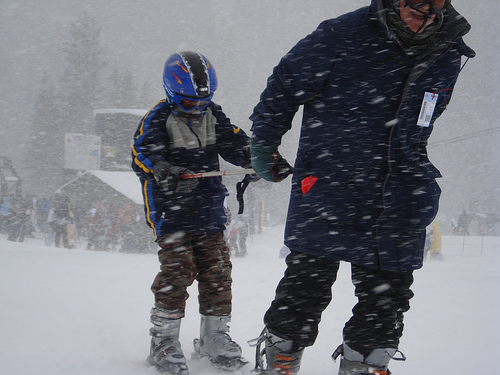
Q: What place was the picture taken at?
A: It was taken at the field.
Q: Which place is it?
A: It is a field.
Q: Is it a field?
A: Yes, it is a field.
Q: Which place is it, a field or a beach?
A: It is a field.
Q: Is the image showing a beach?
A: No, the picture is showing a field.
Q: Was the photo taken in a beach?
A: No, the picture was taken in a field.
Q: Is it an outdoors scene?
A: Yes, it is outdoors.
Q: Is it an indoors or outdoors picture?
A: It is outdoors.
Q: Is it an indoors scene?
A: No, it is outdoors.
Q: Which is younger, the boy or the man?
A: The boy is younger than the man.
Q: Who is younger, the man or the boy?
A: The boy is younger than the man.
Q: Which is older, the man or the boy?
A: The man is older than the boy.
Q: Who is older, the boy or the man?
A: The man is older than the boy.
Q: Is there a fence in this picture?
A: Yes, there is a fence.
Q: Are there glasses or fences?
A: Yes, there is a fence.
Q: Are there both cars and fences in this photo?
A: No, there is a fence but no cars.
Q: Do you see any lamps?
A: No, there are no lamps.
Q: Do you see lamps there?
A: No, there are no lamps.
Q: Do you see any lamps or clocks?
A: No, there are no lamps or clocks.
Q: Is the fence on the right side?
A: Yes, the fence is on the right of the image.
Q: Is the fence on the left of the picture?
A: No, the fence is on the right of the image.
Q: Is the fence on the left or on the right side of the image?
A: The fence is on the right of the image.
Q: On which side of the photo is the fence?
A: The fence is on the right of the image.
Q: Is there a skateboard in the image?
A: No, there are no skateboards.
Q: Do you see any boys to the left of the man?
A: Yes, there is a boy to the left of the man.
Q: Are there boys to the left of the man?
A: Yes, there is a boy to the left of the man.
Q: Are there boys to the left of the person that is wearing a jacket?
A: Yes, there is a boy to the left of the man.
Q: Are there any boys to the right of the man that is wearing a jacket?
A: No, the boy is to the left of the man.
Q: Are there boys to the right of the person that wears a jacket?
A: No, the boy is to the left of the man.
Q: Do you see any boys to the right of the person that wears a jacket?
A: No, the boy is to the left of the man.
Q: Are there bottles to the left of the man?
A: No, there is a boy to the left of the man.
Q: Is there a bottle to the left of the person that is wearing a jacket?
A: No, there is a boy to the left of the man.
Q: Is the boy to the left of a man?
A: Yes, the boy is to the left of a man.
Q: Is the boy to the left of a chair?
A: No, the boy is to the left of a man.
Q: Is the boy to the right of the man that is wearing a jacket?
A: No, the boy is to the left of the man.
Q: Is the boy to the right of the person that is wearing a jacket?
A: No, the boy is to the left of the man.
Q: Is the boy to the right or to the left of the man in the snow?
A: The boy is to the left of the man.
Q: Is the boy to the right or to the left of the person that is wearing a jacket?
A: The boy is to the left of the man.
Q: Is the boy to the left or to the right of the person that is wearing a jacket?
A: The boy is to the left of the man.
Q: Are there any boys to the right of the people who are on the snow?
A: Yes, there is a boy to the right of the people.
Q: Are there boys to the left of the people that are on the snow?
A: No, the boy is to the right of the people.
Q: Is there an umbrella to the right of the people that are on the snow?
A: No, there is a boy to the right of the people.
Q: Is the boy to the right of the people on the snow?
A: Yes, the boy is to the right of the people.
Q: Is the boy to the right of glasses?
A: No, the boy is to the right of the people.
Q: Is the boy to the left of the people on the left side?
A: No, the boy is to the right of the people.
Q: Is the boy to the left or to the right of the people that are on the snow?
A: The boy is to the right of the people.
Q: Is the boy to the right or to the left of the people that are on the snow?
A: The boy is to the right of the people.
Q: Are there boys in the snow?
A: Yes, there is a boy in the snow.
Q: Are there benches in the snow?
A: No, there is a boy in the snow.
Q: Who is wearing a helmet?
A: The boy is wearing a helmet.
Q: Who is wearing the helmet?
A: The boy is wearing a helmet.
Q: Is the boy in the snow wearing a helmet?
A: Yes, the boy is wearing a helmet.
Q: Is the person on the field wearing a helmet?
A: Yes, the boy is wearing a helmet.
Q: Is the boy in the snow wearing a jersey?
A: No, the boy is wearing a helmet.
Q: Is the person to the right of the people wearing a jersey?
A: No, the boy is wearing a helmet.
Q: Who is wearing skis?
A: The boy is wearing skis.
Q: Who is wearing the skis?
A: The boy is wearing skis.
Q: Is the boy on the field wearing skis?
A: Yes, the boy is wearing skis.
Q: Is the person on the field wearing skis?
A: Yes, the boy is wearing skis.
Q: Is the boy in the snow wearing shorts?
A: No, the boy is wearing skis.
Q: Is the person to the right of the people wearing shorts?
A: No, the boy is wearing skis.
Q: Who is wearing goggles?
A: The boy is wearing goggles.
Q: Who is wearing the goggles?
A: The boy is wearing goggles.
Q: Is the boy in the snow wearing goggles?
A: Yes, the boy is wearing goggles.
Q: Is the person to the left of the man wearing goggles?
A: Yes, the boy is wearing goggles.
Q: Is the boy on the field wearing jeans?
A: No, the boy is wearing goggles.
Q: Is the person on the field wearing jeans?
A: No, the boy is wearing goggles.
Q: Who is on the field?
A: The boy is on the field.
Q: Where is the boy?
A: The boy is on the field.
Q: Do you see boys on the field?
A: Yes, there is a boy on the field.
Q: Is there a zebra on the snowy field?
A: No, there is a boy on the field.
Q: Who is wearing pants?
A: The boy is wearing pants.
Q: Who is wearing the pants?
A: The boy is wearing pants.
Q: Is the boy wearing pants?
A: Yes, the boy is wearing pants.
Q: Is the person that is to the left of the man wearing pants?
A: Yes, the boy is wearing pants.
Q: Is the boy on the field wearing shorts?
A: No, the boy is wearing pants.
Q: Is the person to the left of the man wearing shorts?
A: No, the boy is wearing pants.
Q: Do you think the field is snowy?
A: Yes, the field is snowy.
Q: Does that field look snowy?
A: Yes, the field is snowy.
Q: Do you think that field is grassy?
A: No, the field is snowy.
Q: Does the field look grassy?
A: No, the field is snowy.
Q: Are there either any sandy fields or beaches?
A: No, there is a field but it is snowy.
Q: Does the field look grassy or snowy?
A: The field is snowy.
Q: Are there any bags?
A: No, there are no bags.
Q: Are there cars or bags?
A: No, there are no bags or cars.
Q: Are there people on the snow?
A: Yes, there are people on the snow.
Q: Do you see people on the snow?
A: Yes, there are people on the snow.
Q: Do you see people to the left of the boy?
A: Yes, there are people to the left of the boy.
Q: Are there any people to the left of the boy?
A: Yes, there are people to the left of the boy.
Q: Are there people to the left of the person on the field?
A: Yes, there are people to the left of the boy.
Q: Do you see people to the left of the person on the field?
A: Yes, there are people to the left of the boy.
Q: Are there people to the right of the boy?
A: No, the people are to the left of the boy.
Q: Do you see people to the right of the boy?
A: No, the people are to the left of the boy.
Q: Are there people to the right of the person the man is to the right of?
A: No, the people are to the left of the boy.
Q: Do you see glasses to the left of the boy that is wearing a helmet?
A: No, there are people to the left of the boy.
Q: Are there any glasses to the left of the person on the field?
A: No, there are people to the left of the boy.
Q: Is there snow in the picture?
A: Yes, there is snow.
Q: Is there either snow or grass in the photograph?
A: Yes, there is snow.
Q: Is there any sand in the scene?
A: No, there is no sand.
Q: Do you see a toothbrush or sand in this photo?
A: No, there are no sand or toothbrushes.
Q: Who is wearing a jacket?
A: The man is wearing a jacket.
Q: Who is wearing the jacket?
A: The man is wearing a jacket.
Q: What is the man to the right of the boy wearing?
A: The man is wearing a jacket.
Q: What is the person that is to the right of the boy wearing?
A: The man is wearing a jacket.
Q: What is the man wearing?
A: The man is wearing a jacket.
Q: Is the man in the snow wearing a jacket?
A: Yes, the man is wearing a jacket.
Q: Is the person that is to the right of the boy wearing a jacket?
A: Yes, the man is wearing a jacket.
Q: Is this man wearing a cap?
A: No, the man is wearing a jacket.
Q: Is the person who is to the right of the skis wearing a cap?
A: No, the man is wearing a jacket.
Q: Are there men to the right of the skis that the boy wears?
A: Yes, there is a man to the right of the skis.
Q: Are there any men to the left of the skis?
A: No, the man is to the right of the skis.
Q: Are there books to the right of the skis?
A: No, there is a man to the right of the skis.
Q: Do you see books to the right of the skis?
A: No, there is a man to the right of the skis.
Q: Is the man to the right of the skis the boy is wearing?
A: Yes, the man is to the right of the skis.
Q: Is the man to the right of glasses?
A: No, the man is to the right of the skis.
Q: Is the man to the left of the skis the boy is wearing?
A: No, the man is to the right of the skis.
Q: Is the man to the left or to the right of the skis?
A: The man is to the right of the skis.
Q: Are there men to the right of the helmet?
A: Yes, there is a man to the right of the helmet.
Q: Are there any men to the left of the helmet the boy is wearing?
A: No, the man is to the right of the helmet.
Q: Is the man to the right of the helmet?
A: Yes, the man is to the right of the helmet.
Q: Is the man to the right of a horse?
A: No, the man is to the right of the helmet.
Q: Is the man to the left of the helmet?
A: No, the man is to the right of the helmet.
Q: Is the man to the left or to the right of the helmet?
A: The man is to the right of the helmet.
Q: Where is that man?
A: The man is in the snow.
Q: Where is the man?
A: The man is in the snow.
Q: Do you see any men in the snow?
A: Yes, there is a man in the snow.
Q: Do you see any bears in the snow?
A: No, there is a man in the snow.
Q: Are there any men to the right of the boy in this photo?
A: Yes, there is a man to the right of the boy.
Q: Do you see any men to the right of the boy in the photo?
A: Yes, there is a man to the right of the boy.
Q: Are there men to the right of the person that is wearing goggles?
A: Yes, there is a man to the right of the boy.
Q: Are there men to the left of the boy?
A: No, the man is to the right of the boy.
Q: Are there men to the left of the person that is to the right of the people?
A: No, the man is to the right of the boy.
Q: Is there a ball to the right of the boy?
A: No, there is a man to the right of the boy.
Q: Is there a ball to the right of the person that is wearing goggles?
A: No, there is a man to the right of the boy.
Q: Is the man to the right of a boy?
A: Yes, the man is to the right of a boy.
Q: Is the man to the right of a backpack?
A: No, the man is to the right of a boy.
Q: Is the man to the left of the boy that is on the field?
A: No, the man is to the right of the boy.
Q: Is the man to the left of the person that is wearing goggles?
A: No, the man is to the right of the boy.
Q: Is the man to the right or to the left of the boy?
A: The man is to the right of the boy.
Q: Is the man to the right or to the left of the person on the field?
A: The man is to the right of the boy.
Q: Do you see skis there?
A: Yes, there are skis.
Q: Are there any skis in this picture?
A: Yes, there are skis.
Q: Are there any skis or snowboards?
A: Yes, there are skis.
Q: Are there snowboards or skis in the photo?
A: Yes, there are skis.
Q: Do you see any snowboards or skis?
A: Yes, there are skis.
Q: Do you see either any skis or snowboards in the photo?
A: Yes, there are skis.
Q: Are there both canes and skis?
A: No, there are skis but no canes.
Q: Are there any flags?
A: No, there are no flags.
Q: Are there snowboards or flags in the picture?
A: No, there are no flags or snowboards.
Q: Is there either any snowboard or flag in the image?
A: No, there are no flags or snowboards.